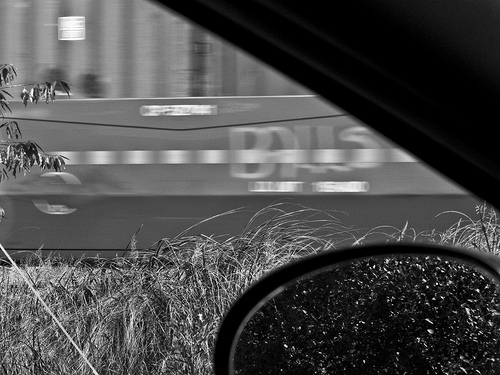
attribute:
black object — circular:
[205, 237, 496, 369]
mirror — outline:
[236, 253, 497, 368]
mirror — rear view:
[254, 243, 498, 367]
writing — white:
[134, 101, 224, 120]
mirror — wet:
[210, 224, 499, 373]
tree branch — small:
[7, 77, 78, 109]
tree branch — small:
[4, 133, 69, 185]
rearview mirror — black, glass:
[207, 220, 498, 372]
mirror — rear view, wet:
[211, 239, 498, 371]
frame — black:
[207, 237, 498, 373]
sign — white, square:
[54, 13, 87, 42]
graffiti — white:
[228, 124, 382, 180]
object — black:
[197, 234, 496, 366]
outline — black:
[186, 225, 493, 372]